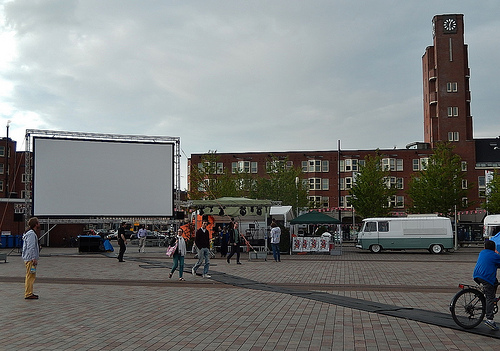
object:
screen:
[32, 141, 179, 216]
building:
[185, 12, 500, 246]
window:
[446, 107, 453, 118]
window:
[313, 160, 322, 172]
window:
[247, 161, 258, 176]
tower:
[188, 10, 483, 233]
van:
[356, 213, 456, 253]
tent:
[286, 209, 345, 225]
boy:
[469, 238, 499, 330]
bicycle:
[448, 283, 499, 335]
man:
[21, 216, 47, 303]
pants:
[21, 259, 40, 297]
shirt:
[21, 231, 40, 263]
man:
[191, 218, 215, 278]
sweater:
[194, 230, 213, 250]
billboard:
[22, 132, 185, 227]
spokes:
[451, 290, 487, 330]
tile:
[257, 309, 281, 330]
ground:
[0, 243, 500, 343]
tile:
[212, 318, 228, 331]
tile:
[132, 321, 149, 332]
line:
[288, 312, 302, 324]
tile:
[286, 318, 301, 330]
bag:
[164, 237, 179, 263]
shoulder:
[176, 237, 179, 244]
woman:
[166, 227, 189, 283]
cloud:
[0, 9, 43, 115]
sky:
[0, 0, 500, 142]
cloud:
[1, 0, 500, 148]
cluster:
[191, 142, 500, 216]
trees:
[188, 147, 240, 207]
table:
[75, 235, 104, 255]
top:
[75, 235, 100, 239]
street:
[1, 237, 499, 347]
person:
[468, 237, 499, 332]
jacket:
[472, 249, 500, 286]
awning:
[284, 208, 342, 226]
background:
[0, 0, 499, 153]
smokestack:
[5, 119, 11, 197]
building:
[2, 135, 31, 263]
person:
[190, 214, 218, 281]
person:
[165, 225, 189, 285]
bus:
[356, 211, 457, 255]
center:
[9, 182, 499, 270]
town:
[0, 0, 500, 351]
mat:
[299, 280, 409, 322]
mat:
[207, 260, 256, 296]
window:
[479, 174, 488, 183]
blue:
[470, 248, 499, 288]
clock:
[444, 19, 459, 33]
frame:
[22, 134, 183, 227]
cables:
[286, 283, 414, 310]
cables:
[204, 268, 259, 289]